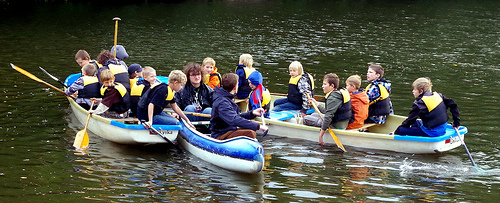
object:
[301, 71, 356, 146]
kids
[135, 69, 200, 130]
children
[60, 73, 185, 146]
canoe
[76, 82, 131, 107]
life jackets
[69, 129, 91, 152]
oar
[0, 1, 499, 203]
ripples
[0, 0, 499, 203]
river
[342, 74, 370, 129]
child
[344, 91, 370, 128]
life vest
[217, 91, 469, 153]
boat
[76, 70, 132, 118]
child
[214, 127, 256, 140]
pants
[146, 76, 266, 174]
boat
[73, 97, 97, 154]
paddle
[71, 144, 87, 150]
tip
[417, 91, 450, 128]
life preserver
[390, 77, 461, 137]
boy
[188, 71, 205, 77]
glasses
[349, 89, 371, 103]
hood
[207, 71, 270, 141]
man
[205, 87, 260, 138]
coat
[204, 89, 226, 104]
hood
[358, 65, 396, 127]
people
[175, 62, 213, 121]
girl